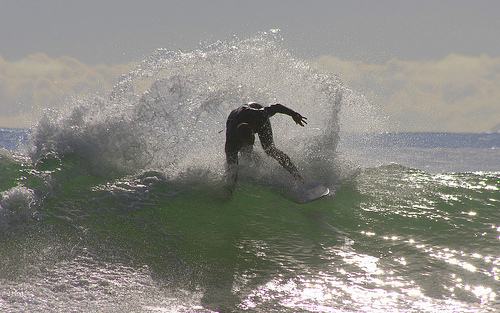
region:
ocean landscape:
[18, 25, 429, 300]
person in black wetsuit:
[221, 87, 316, 227]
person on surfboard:
[183, 67, 350, 243]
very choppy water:
[378, 152, 481, 291]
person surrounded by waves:
[148, 75, 361, 218]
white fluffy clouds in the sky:
[398, 28, 498, 145]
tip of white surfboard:
[241, 177, 347, 206]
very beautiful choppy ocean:
[16, 75, 201, 292]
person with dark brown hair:
[213, 70, 314, 208]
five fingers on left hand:
[208, 95, 318, 147]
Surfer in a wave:
[205, 68, 340, 224]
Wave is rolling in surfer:
[0, 51, 447, 245]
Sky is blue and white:
[9, 10, 499, 138]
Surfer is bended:
[211, 91, 316, 198]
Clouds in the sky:
[0, 54, 497, 130]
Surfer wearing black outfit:
[201, 96, 319, 198]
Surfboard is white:
[248, 171, 347, 206]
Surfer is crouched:
[210, 91, 320, 200]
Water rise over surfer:
[99, 22, 376, 112]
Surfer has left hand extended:
[214, 93, 334, 205]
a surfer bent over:
[211, 100, 341, 209]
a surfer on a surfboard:
[212, 100, 344, 218]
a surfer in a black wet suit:
[220, 101, 292, 180]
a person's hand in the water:
[201, 170, 244, 205]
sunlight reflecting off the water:
[314, 248, 376, 288]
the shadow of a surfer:
[176, 223, 264, 302]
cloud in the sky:
[23, 47, 73, 79]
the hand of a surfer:
[290, 108, 306, 130]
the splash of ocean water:
[125, 62, 185, 116]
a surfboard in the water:
[273, 169, 348, 216]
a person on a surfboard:
[211, 96, 336, 208]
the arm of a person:
[266, 95, 292, 120]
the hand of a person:
[293, 110, 306, 125]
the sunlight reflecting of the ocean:
[315, 260, 380, 300]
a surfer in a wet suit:
[215, 96, 305, 188]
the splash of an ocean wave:
[137, 58, 209, 100]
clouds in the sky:
[25, 47, 89, 87]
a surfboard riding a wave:
[266, 172, 346, 208]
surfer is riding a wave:
[221, 104, 330, 214]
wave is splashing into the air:
[39, 40, 381, 199]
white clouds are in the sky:
[2, 51, 496, 125]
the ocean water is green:
[4, 153, 496, 308]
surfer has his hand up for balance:
[264, 100, 311, 130]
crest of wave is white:
[0, 30, 388, 205]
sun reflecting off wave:
[254, 230, 498, 307]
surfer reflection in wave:
[189, 236, 271, 311]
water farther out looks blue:
[4, 125, 495, 171]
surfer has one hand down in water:
[217, 134, 244, 210]